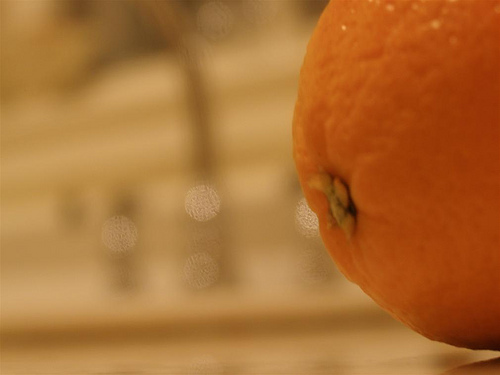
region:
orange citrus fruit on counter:
[291, 4, 495, 351]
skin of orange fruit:
[383, 263, 416, 318]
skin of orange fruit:
[422, 232, 462, 284]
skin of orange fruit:
[447, 298, 483, 342]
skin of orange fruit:
[401, 171, 421, 216]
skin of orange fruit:
[434, 162, 488, 219]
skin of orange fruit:
[329, 100, 375, 148]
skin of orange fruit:
[437, 117, 487, 159]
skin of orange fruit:
[381, 33, 431, 81]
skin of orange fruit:
[318, 137, 350, 182]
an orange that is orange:
[248, 11, 493, 273]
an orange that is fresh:
[251, 19, 480, 369]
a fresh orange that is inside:
[219, 3, 478, 369]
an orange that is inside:
[262, 13, 469, 372]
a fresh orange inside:
[234, 13, 429, 372]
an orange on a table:
[272, 21, 499, 358]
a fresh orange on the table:
[269, 18, 497, 369]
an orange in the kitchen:
[69, 12, 496, 339]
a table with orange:
[142, 14, 497, 358]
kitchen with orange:
[64, 23, 496, 318]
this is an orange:
[290, 9, 482, 271]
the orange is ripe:
[395, 20, 480, 282]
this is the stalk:
[308, 175, 362, 237]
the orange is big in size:
[374, 11, 474, 317]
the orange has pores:
[377, 28, 466, 174]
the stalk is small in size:
[312, 175, 352, 238]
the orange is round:
[299, 11, 477, 303]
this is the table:
[269, 333, 354, 372]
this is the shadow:
[478, 358, 497, 373]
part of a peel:
[321, 44, 364, 109]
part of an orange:
[398, 247, 433, 332]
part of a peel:
[415, 185, 446, 260]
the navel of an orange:
[299, 153, 367, 229]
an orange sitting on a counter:
[249, 0, 497, 368]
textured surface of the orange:
[396, 140, 469, 277]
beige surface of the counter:
[132, 331, 379, 373]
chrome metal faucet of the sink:
[44, 42, 312, 289]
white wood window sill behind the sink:
[92, 37, 289, 148]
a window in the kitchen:
[84, 0, 283, 60]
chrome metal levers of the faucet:
[76, 185, 355, 302]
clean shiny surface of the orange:
[293, 0, 490, 115]